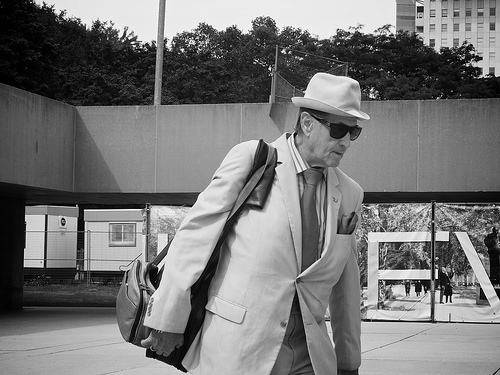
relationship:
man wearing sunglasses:
[142, 71, 368, 374] [312, 114, 363, 143]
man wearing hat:
[142, 71, 368, 374] [291, 71, 370, 122]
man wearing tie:
[142, 71, 368, 374] [301, 168, 323, 270]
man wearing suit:
[142, 71, 368, 374] [142, 132, 361, 374]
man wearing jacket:
[142, 71, 368, 374] [142, 132, 361, 374]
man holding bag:
[142, 71, 368, 374] [113, 262, 175, 345]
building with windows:
[396, 1, 499, 80] [415, 6, 495, 75]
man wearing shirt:
[142, 71, 368, 374] [285, 132, 327, 263]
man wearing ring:
[142, 71, 368, 374] [149, 346, 155, 352]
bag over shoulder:
[113, 262, 175, 345] [229, 134, 271, 187]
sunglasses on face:
[312, 114, 363, 143] [298, 105, 358, 168]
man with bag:
[142, 71, 368, 374] [113, 262, 175, 345]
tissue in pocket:
[339, 212, 358, 234] [335, 232, 352, 261]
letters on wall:
[368, 230, 499, 317] [1, 85, 499, 320]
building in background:
[396, 1, 499, 80] [1, 1, 499, 98]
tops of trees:
[0, 1, 480, 100] [1, 1, 498, 104]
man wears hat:
[142, 71, 368, 374] [291, 71, 370, 122]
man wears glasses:
[142, 71, 368, 374] [312, 114, 363, 143]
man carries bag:
[142, 71, 368, 374] [113, 262, 175, 345]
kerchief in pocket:
[339, 212, 358, 234] [335, 232, 352, 261]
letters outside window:
[368, 230, 499, 317] [355, 202, 499, 323]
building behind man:
[396, 1, 499, 80] [142, 71, 368, 374]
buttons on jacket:
[280, 273, 301, 328] [142, 132, 361, 374]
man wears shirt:
[142, 71, 368, 374] [285, 132, 327, 263]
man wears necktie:
[142, 71, 368, 374] [301, 168, 323, 270]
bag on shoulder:
[113, 262, 175, 345] [229, 134, 271, 187]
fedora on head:
[291, 71, 370, 122] [298, 105, 358, 168]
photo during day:
[0, 1, 499, 375] [32, 1, 399, 41]